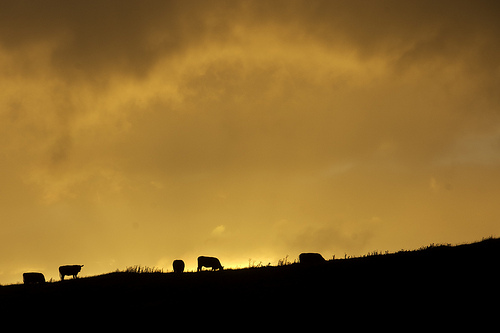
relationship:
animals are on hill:
[17, 255, 326, 284] [1, 229, 498, 331]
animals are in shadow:
[17, 255, 326, 284] [17, 273, 466, 291]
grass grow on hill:
[109, 265, 166, 276] [1, 229, 498, 331]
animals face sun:
[57, 263, 86, 281] [204, 218, 285, 271]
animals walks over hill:
[57, 263, 86, 281] [1, 229, 498, 331]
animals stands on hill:
[57, 263, 86, 281] [1, 229, 498, 331]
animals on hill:
[57, 263, 86, 281] [1, 229, 498, 331]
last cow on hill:
[294, 246, 338, 264] [1, 229, 498, 331]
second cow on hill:
[193, 249, 237, 271] [1, 229, 498, 331]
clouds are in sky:
[73, 54, 434, 185] [3, 4, 483, 259]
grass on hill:
[109, 261, 166, 280] [1, 229, 498, 331]